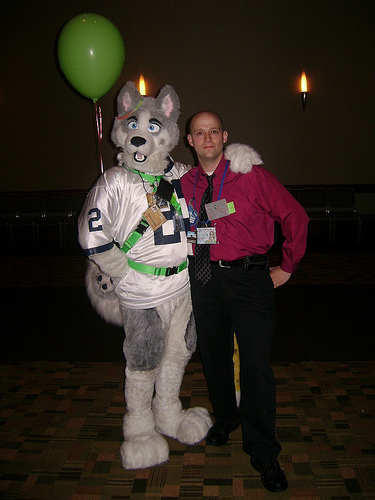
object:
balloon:
[58, 13, 126, 104]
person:
[77, 81, 263, 470]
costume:
[77, 81, 212, 469]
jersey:
[77, 162, 190, 309]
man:
[180, 111, 309, 492]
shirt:
[180, 151, 309, 275]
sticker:
[205, 199, 230, 221]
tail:
[84, 259, 122, 327]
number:
[88, 208, 103, 232]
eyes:
[127, 122, 138, 130]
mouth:
[134, 151, 148, 162]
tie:
[194, 173, 215, 287]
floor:
[3, 257, 374, 499]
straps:
[120, 165, 188, 277]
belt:
[188, 255, 269, 269]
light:
[300, 70, 308, 112]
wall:
[1, 1, 374, 243]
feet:
[250, 453, 288, 491]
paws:
[120, 430, 170, 469]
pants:
[186, 253, 282, 463]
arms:
[256, 170, 309, 273]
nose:
[131, 136, 147, 147]